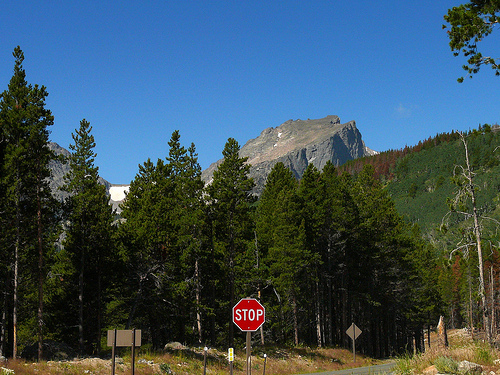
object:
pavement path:
[327, 341, 434, 374]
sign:
[233, 297, 266, 331]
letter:
[235, 309, 242, 321]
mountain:
[198, 114, 378, 194]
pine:
[267, 186, 319, 345]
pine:
[117, 157, 157, 268]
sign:
[105, 329, 143, 348]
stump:
[436, 314, 448, 347]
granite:
[278, 124, 322, 146]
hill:
[277, 133, 494, 327]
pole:
[262, 355, 267, 375]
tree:
[201, 135, 258, 352]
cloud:
[390, 104, 412, 116]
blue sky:
[0, 0, 500, 186]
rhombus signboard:
[346, 322, 363, 340]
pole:
[352, 323, 355, 364]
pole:
[245, 329, 252, 375]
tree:
[112, 129, 214, 345]